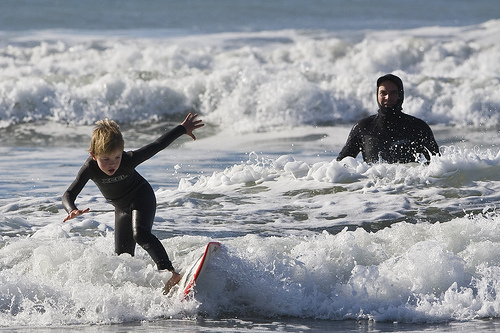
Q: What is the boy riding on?
A: Surfboard.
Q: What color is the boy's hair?
A: Blonde.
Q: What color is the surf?
A: Water.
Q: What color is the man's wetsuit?
A: Black.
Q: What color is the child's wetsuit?
A: Black.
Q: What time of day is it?
A: Noon.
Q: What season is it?
A: Summer.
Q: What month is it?
A: June.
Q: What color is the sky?
A: Blue.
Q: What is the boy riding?
A: A surfboard.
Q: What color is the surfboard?
A: White and red.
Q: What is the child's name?
A: Zack.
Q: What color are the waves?
A: White.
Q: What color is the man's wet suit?
A: Black.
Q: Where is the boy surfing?
A: Ocean.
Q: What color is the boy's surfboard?
A: Red and white.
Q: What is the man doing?
A: Watching boy.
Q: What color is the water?
A: Blue and white.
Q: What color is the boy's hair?
A: Red.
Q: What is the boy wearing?
A: A wetsuit.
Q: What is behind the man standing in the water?
A: Waves.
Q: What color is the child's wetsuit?
A: Black.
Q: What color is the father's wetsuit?
A: Black.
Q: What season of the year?
A: Summer.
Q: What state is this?
A: South Carolina.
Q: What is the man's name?
A: Jake.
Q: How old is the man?
A: 40.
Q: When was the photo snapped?
A: At noon.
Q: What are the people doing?
A: Surfing.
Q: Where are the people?
A: In water.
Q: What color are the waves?
A: White.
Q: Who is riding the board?
A: A boy.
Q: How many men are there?
A: One.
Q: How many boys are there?
A: One.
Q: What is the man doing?
A: Watching the kid surf.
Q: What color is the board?
A: White and red.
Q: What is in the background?
A: Water.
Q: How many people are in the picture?
A: 2.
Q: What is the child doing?
A: Surfing.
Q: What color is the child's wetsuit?
A: Black.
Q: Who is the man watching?
A: Child.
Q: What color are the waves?
A: White.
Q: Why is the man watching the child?
A: Teaching to ride surfboard.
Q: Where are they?
A: In water.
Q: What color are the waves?
A: White.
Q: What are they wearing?
A: Wetsuits.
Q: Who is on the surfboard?
A: Child.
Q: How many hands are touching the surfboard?
A: None.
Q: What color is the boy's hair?
A: Brown.